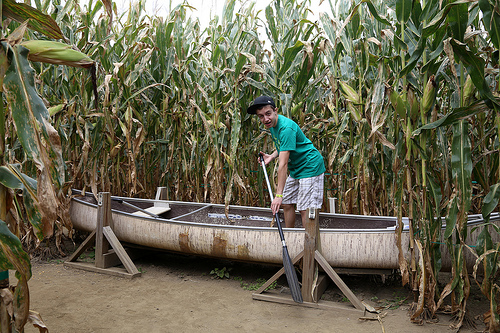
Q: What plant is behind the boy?
A: Corn.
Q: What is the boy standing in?
A: A boat.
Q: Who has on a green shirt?
A: The boy.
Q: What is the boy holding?
A: An oar.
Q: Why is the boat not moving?
A: It is on a boat stand.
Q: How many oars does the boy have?
A: One.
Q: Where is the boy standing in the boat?
A: In the middle.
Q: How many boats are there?
A: One.